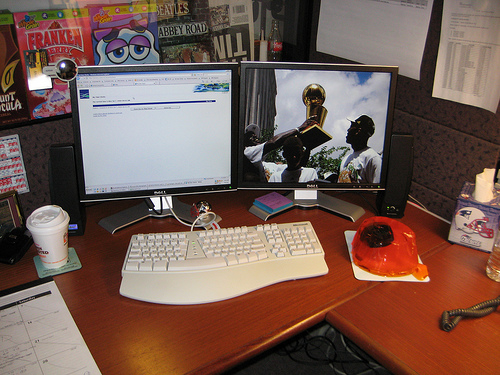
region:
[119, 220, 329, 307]
A white colored keyboard.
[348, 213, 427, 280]
A orange colored item.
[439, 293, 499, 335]
A gray coiled cord.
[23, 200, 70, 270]
A white coffee cup.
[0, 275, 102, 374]
A white desk calendar.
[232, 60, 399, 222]
Silver and black monitor.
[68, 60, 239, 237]
A functioning computer monitor.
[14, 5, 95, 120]
A pink cereal box.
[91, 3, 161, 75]
Blue and purple box.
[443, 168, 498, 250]
A blue and white tissue box.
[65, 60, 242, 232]
A computer monitor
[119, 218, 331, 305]
A white keyboard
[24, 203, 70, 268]
A white paper coffee cup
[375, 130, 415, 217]
A black computer speaker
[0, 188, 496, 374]
A wooden corner desk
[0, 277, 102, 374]
A desk top calendar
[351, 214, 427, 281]
An orange bag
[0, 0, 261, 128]
A collage of posters handing on the wall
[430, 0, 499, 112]
A piece of paper hanging on the wall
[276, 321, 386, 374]
A tangled set of electronics cords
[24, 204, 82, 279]
Coffee cup sitting on a green coaster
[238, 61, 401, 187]
Computer monitor with a moving being played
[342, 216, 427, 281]
Red computer mouse on a white mousepad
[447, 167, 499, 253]
Tissue box with a sports team logo on it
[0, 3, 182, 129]
Row of cereal boxes on display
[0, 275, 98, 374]
Calendar that has been written on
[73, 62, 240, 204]
Computer monitor with a webpage displayed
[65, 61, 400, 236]
Two computer monitors on stands side by side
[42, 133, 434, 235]
Two standing computer speakers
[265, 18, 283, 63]
Clear soda bottle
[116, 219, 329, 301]
white computer keyboard on desk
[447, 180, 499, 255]
tissue box on desk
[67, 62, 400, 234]
dual computer monitors on desk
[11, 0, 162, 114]
cereal boxes on shelf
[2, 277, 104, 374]
paper calendar on desk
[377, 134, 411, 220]
black speaker on desk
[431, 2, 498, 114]
white paper on wall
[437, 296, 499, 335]
grey phone cord on desk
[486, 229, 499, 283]
bottle of water on desk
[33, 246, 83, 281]
cup holder on desk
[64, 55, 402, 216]
two computer screens together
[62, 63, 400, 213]
two computer screens side by side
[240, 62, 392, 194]
one square computer screen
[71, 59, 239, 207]
a square computer screen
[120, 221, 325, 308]
white key board on desk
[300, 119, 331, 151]
book on the screen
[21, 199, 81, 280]
cup of coffee on desk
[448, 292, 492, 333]
cord to phone no desk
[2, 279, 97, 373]
large paper calendar on the desk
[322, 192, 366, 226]
silver stand to monitor